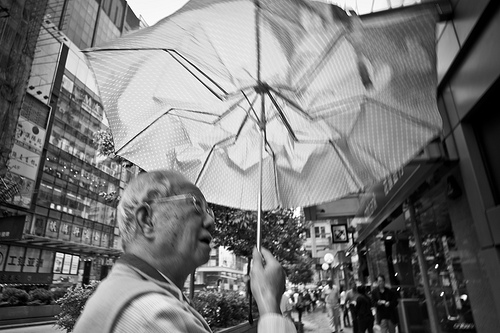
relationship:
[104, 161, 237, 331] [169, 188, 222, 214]
man wearing eyeglasses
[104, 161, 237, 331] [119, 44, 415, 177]
man holding umbrella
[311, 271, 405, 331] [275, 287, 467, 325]
people on corner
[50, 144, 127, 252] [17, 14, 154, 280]
windows on building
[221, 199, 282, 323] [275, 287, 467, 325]
tree on corner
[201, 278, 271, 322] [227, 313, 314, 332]
bushes on side of street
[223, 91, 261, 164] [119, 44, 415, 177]
wire of umbrella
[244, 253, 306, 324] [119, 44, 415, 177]
hand holding umbrella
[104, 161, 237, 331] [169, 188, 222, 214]
man with eyeglasses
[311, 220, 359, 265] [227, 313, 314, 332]
signs of street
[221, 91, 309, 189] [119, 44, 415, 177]
support on umbrella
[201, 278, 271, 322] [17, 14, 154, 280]
bushes near building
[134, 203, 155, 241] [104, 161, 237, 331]
ear on man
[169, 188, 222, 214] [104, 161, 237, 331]
eyeglasses on man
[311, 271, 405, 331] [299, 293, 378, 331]
people are on sidewalk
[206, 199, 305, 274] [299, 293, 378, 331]
tree along sidewalk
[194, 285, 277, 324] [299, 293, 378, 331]
shrubs on sidewalk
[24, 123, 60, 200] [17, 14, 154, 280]
banner hanging from building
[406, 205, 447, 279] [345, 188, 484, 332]
window on store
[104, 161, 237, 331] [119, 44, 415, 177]
man with umbrella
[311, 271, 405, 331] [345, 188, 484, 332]
people are near store